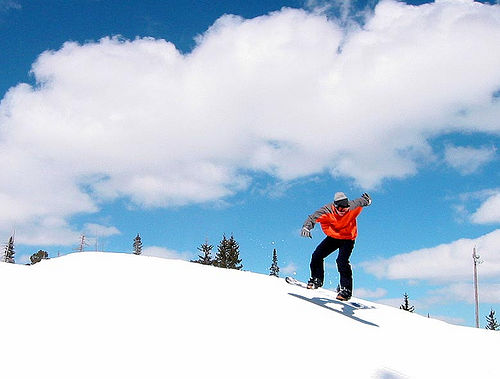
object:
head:
[333, 191, 351, 217]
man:
[300, 192, 372, 301]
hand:
[300, 228, 313, 239]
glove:
[299, 226, 313, 240]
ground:
[0, 252, 499, 376]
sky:
[1, 1, 500, 193]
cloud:
[2, 0, 499, 246]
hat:
[333, 191, 348, 201]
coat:
[302, 196, 369, 241]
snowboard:
[285, 275, 369, 311]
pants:
[309, 235, 356, 292]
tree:
[29, 249, 50, 265]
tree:
[132, 232, 144, 256]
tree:
[190, 239, 218, 267]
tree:
[212, 231, 245, 270]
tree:
[269, 248, 280, 278]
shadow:
[310, 297, 376, 316]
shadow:
[287, 291, 380, 327]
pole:
[472, 246, 481, 328]